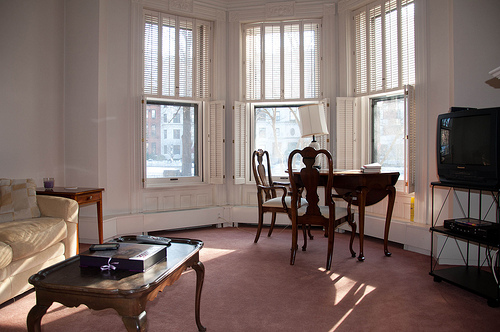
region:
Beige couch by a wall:
[3, 195, 105, 302]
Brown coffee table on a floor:
[74, 222, 187, 329]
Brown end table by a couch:
[28, 178, 145, 264]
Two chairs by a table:
[243, 152, 418, 257]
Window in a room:
[133, 96, 223, 192]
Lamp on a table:
[292, 106, 360, 165]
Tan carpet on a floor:
[210, 238, 367, 322]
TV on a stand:
[429, 107, 499, 303]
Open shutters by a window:
[119, 94, 285, 219]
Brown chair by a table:
[282, 148, 379, 260]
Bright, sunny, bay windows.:
[122, 5, 425, 186]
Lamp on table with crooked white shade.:
[292, 100, 327, 166]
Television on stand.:
[432, 110, 494, 185]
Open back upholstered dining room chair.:
[282, 145, 358, 265]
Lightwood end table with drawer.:
[35, 180, 105, 250]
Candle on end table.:
[36, 172, 61, 197]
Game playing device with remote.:
[72, 236, 167, 271]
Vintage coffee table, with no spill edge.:
[25, 230, 215, 330]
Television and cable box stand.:
[427, 176, 494, 301]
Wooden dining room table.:
[283, 167, 394, 260]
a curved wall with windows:
[105, 0, 448, 238]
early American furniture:
[240, 141, 402, 266]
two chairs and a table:
[238, 140, 405, 269]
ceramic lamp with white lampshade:
[297, 96, 331, 176]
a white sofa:
[1, 177, 81, 299]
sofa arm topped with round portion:
[37, 187, 82, 282]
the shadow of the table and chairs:
[148, 243, 379, 327]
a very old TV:
[423, 97, 498, 202]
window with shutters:
[237, 10, 331, 100]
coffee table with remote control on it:
[22, 220, 227, 330]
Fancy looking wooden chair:
[287, 147, 357, 273]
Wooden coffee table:
[27, 230, 212, 330]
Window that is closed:
[141, 96, 206, 188]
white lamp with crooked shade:
[294, 103, 329, 166]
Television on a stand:
[435, 111, 499, 190]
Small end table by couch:
[37, 178, 104, 259]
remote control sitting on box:
[87, 240, 122, 250]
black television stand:
[425, 173, 499, 306]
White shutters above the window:
[236, 11, 328, 103]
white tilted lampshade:
[298, 102, 328, 139]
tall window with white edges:
[130, 0, 226, 190]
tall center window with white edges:
[226, 3, 331, 188]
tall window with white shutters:
[336, 2, 418, 197]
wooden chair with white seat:
[247, 148, 308, 250]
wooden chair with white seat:
[286, 146, 356, 271]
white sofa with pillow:
[0, 177, 81, 309]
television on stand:
[427, 105, 497, 307]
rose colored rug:
[0, 225, 497, 329]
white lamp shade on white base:
[296, 101, 328, 168]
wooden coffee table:
[26, 232, 204, 329]